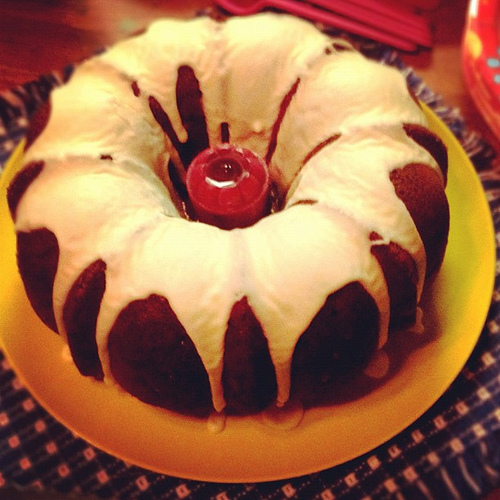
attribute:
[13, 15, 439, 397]
cake — round, white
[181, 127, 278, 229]
candle — red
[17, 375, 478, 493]
table — blue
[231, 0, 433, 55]
spoons — red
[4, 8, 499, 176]
table — brown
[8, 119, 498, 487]
plate — yellow, plastic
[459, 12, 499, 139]
plates — red